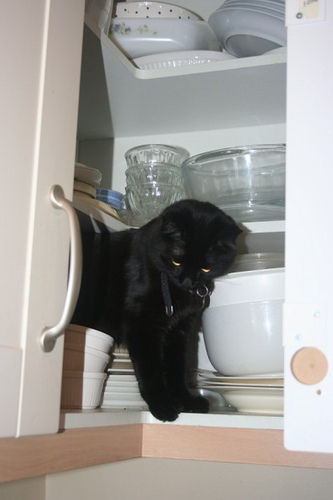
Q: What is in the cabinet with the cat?
A: Dishes.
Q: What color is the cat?
A: Black.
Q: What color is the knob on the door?
A: Pink.